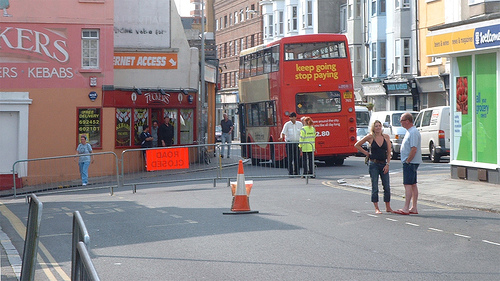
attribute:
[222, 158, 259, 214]
traffic cone — orange, white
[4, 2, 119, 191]
building — peach, pink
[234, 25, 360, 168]
doubledecker bus — red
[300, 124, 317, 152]
safety shirt — yellow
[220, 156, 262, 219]
cone — orange, white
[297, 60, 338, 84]
sign — yellow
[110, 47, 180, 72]
sign — access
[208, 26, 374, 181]
bus — red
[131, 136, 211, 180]
sign — bright orange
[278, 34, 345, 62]
window — rear, upper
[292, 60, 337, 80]
writing — yellow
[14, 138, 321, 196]
fencing — temporary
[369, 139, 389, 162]
shirt — black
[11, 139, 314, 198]
barrier — metal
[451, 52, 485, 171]
window — green